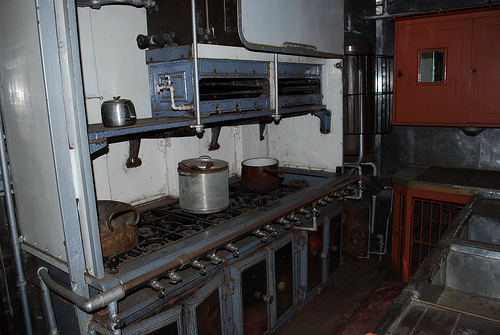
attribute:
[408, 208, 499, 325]
sink — old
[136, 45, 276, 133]
oven — old, metal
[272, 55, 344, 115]
oven — old, metal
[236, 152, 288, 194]
kettle — silver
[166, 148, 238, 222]
kettle — silver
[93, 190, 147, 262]
kettle — silver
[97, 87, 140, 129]
kettle — silver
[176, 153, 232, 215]
pot — silver, tall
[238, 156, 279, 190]
pot — brown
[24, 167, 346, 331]
stove — rusty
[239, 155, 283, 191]
pot — black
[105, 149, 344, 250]
stove — old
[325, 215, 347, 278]
cabinets — rusted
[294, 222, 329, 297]
cabinets — rusted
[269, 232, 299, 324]
cabinets — rusted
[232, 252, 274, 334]
cabinets — rusted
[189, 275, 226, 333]
cabinets — rusted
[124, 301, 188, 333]
cabinets — rusted